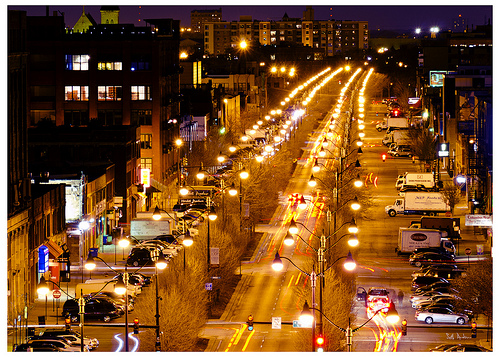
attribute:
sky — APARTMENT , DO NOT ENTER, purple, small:
[15, 5, 492, 43]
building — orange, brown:
[184, 14, 381, 65]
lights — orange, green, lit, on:
[100, 57, 389, 352]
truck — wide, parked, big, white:
[379, 187, 453, 216]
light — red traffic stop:
[374, 107, 411, 194]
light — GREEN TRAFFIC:
[209, 118, 232, 141]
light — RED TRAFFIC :
[381, 104, 401, 157]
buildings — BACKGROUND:
[24, 37, 212, 235]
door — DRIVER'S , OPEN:
[413, 305, 460, 331]